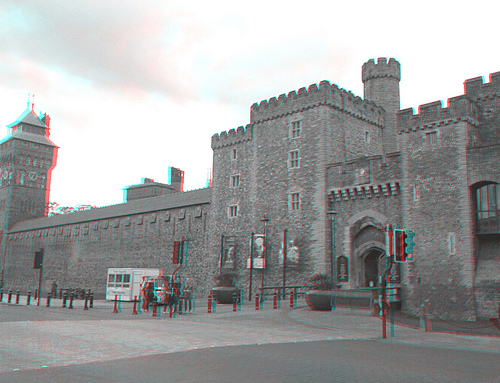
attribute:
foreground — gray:
[188, 343, 396, 373]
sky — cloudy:
[78, 40, 281, 89]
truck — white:
[87, 257, 194, 312]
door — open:
[339, 216, 410, 313]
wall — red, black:
[102, 235, 173, 272]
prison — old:
[190, 45, 410, 305]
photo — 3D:
[6, 2, 491, 382]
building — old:
[206, 45, 475, 314]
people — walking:
[137, 267, 198, 317]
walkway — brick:
[19, 305, 359, 361]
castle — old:
[197, 45, 491, 323]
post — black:
[33, 240, 45, 307]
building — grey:
[6, 47, 498, 332]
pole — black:
[372, 218, 395, 338]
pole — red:
[377, 224, 397, 340]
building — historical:
[199, 47, 497, 337]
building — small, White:
[5, 60, 469, 350]